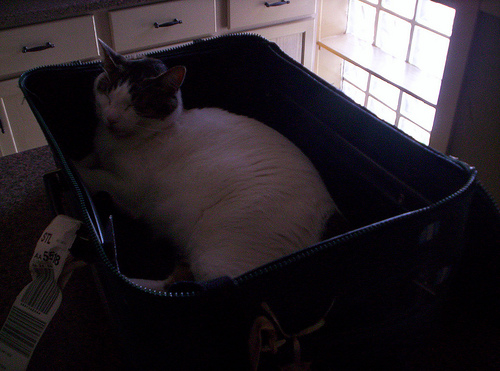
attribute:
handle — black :
[153, 17, 181, 28]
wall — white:
[435, 8, 498, 193]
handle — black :
[269, 0, 287, 15]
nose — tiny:
[101, 110, 124, 129]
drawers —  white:
[12, 4, 344, 127]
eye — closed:
[98, 84, 109, 102]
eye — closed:
[124, 99, 138, 112]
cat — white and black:
[72, 38, 357, 287]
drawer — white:
[2, 17, 99, 71]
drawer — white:
[227, 0, 317, 30]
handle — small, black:
[22, 38, 54, 55]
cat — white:
[85, 38, 321, 294]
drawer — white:
[224, 0, 320, 35]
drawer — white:
[105, 1, 220, 57]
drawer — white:
[0, 10, 107, 81]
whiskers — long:
[68, 94, 173, 147]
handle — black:
[20, 38, 58, 57]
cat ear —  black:
[155, 56, 197, 92]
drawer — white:
[111, 0, 218, 52]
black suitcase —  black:
[17, 32, 499, 368]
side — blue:
[358, 240, 415, 272]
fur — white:
[132, 114, 334, 276]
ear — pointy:
[142, 62, 190, 99]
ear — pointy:
[94, 35, 131, 80]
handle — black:
[21, 43, 53, 52]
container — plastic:
[18, 33, 485, 347]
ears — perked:
[93, 37, 130, 80]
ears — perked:
[142, 60, 194, 101]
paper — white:
[0, 210, 88, 370]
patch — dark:
[90, 47, 183, 121]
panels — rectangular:
[317, 0, 465, 170]